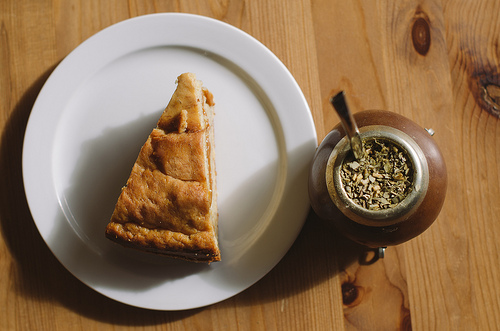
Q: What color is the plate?
A: White.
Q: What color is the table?
A: Brown.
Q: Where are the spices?
A: Next to plate.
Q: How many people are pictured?
A: 0.